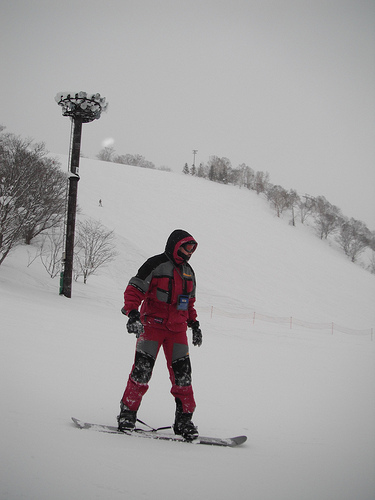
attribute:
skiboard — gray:
[69, 382, 311, 477]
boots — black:
[97, 400, 212, 436]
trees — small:
[226, 158, 373, 259]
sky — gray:
[46, 10, 369, 114]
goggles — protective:
[174, 240, 208, 260]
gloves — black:
[111, 310, 216, 354]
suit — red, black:
[121, 260, 227, 394]